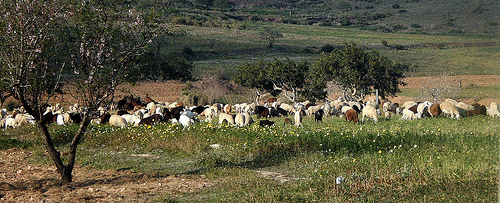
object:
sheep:
[437, 100, 463, 121]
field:
[1, 31, 500, 202]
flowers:
[263, 122, 297, 139]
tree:
[0, 0, 190, 181]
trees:
[312, 42, 413, 109]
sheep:
[344, 108, 358, 122]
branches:
[7, 82, 66, 168]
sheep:
[360, 102, 384, 123]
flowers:
[123, 0, 150, 35]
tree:
[256, 21, 286, 48]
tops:
[330, 42, 381, 55]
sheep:
[314, 109, 326, 121]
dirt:
[1, 150, 198, 202]